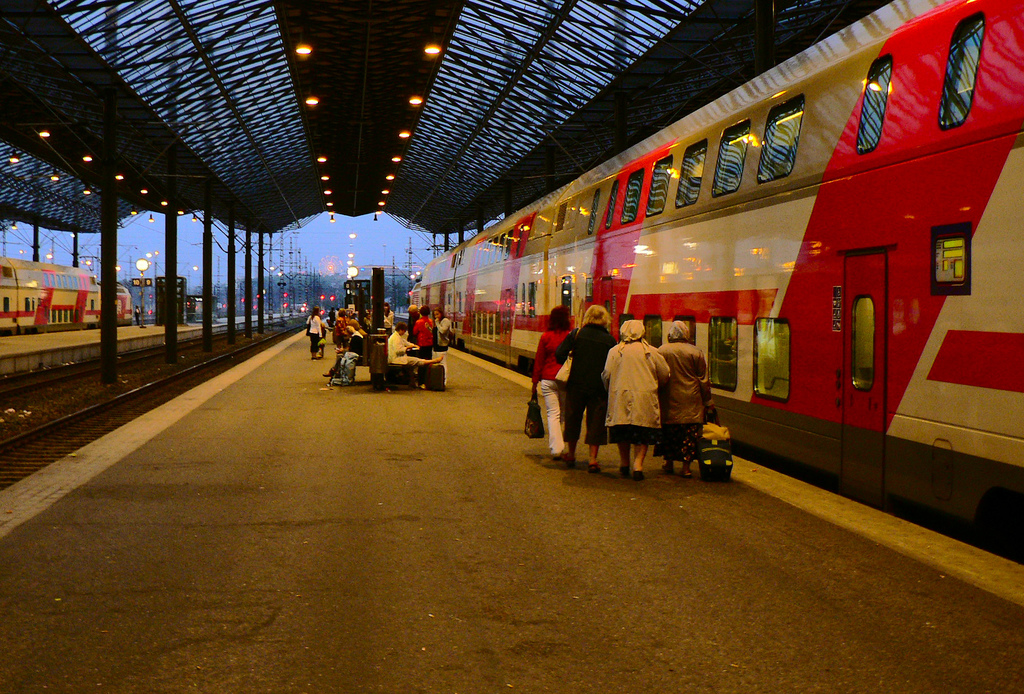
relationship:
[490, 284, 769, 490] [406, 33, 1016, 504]
old women getting on train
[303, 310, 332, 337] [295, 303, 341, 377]
shirt on person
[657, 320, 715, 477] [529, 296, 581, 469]
lady getting on woman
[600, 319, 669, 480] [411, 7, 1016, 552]
lady getting on train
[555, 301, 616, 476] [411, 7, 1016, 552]
woman getting on train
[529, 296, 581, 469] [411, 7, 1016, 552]
woman getting on train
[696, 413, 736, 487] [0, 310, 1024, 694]
luggage on platform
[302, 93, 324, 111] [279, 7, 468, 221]
light hanging from ceiling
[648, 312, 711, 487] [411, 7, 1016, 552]
lady walking beside train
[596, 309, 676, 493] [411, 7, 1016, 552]
lady walking beside train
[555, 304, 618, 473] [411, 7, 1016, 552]
woman walking beside train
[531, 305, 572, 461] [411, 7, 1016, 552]
woman walking beside train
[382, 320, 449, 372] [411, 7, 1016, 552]
person waiting for train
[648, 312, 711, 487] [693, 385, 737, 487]
lady pulling luggage